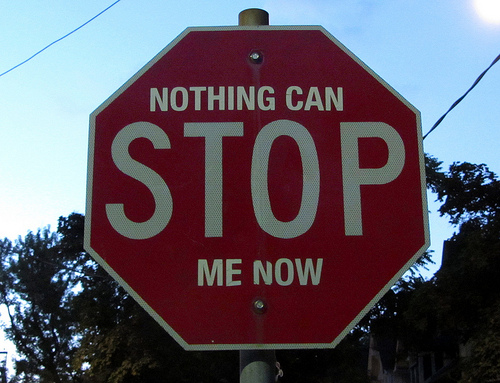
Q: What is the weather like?
A: It is clear.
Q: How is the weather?
A: It is clear.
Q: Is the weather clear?
A: Yes, it is clear.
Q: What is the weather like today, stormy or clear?
A: It is clear.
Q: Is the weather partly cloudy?
A: No, it is clear.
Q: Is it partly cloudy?
A: No, it is clear.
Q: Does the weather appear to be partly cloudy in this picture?
A: No, it is clear.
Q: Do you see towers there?
A: No, there are no towers.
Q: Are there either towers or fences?
A: No, there are no towers or fences.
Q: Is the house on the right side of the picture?
A: Yes, the house is on the right of the image.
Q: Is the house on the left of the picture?
A: No, the house is on the right of the image.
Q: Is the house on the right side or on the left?
A: The house is on the right of the image.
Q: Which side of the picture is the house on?
A: The house is on the right of the image.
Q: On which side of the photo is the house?
A: The house is on the right of the image.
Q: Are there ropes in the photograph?
A: No, there are no ropes.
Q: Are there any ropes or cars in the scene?
A: No, there are no ropes or cars.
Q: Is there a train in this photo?
A: No, there are no trains.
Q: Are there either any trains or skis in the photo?
A: No, there are no trains or skis.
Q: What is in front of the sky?
A: The wire is in front of the sky.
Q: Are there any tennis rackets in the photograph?
A: No, there are no tennis rackets.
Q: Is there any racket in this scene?
A: No, there are no rackets.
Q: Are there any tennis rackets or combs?
A: No, there are no tennis rackets or combs.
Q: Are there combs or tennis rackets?
A: No, there are no tennis rackets or combs.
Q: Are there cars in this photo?
A: No, there are no cars.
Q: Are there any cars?
A: No, there are no cars.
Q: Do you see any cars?
A: No, there are no cars.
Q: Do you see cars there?
A: No, there are no cars.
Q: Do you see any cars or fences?
A: No, there are no cars or fences.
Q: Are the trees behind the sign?
A: Yes, the trees are behind the sign.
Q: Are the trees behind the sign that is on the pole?
A: Yes, the trees are behind the sign.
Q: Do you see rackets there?
A: No, there are no rackets.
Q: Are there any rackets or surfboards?
A: No, there are no rackets or surfboards.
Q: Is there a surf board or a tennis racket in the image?
A: No, there are no rackets or surfboards.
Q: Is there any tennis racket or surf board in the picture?
A: No, there are no rackets or surfboards.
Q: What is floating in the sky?
A: The clouds are floating in the sky.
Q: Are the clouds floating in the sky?
A: Yes, the clouds are floating in the sky.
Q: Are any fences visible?
A: No, there are no fences.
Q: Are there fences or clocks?
A: No, there are no fences or clocks.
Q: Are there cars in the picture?
A: No, there are no cars.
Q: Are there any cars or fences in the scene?
A: No, there are no cars or fences.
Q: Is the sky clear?
A: Yes, the sky is clear.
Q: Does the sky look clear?
A: Yes, the sky is clear.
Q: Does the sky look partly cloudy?
A: No, the sky is clear.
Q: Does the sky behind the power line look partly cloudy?
A: No, the sky is clear.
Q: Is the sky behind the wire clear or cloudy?
A: The sky is clear.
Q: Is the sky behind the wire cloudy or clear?
A: The sky is clear.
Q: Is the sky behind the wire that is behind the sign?
A: Yes, the sky is behind the powerline.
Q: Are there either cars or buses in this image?
A: No, there are no cars or buses.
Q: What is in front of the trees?
A: The sign is in front of the trees.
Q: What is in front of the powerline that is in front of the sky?
A: The sign is in front of the wire.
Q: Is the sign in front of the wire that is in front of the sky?
A: Yes, the sign is in front of the wire.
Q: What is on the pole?
A: The sign is on the pole.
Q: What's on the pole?
A: The sign is on the pole.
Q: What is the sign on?
A: The sign is on the pole.